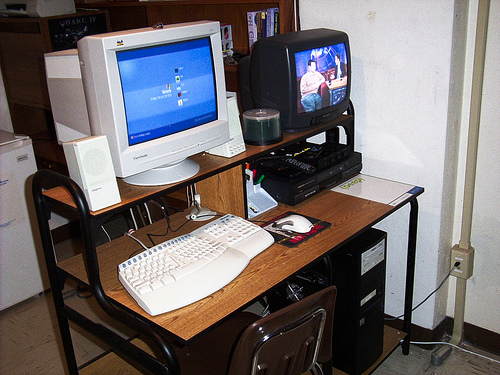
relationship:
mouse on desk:
[271, 214, 314, 234] [30, 98, 423, 369]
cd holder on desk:
[243, 108, 283, 145] [27, 21, 422, 373]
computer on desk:
[52, 48, 260, 138] [79, 213, 452, 314]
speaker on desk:
[62, 134, 122, 213] [79, 213, 452, 314]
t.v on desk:
[235, 27, 351, 133] [30, 98, 423, 369]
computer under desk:
[266, 227, 388, 374] [65, 235, 225, 371]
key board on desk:
[116, 212, 275, 317] [30, 98, 423, 369]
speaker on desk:
[60, 132, 124, 212] [30, 98, 423, 369]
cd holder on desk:
[243, 108, 283, 145] [30, 98, 423, 369]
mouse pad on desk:
[258, 211, 332, 247] [30, 98, 423, 369]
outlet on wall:
[448, 245, 477, 277] [295, 5, 497, 355]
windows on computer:
[145, 79, 172, 103] [40, 17, 248, 214]